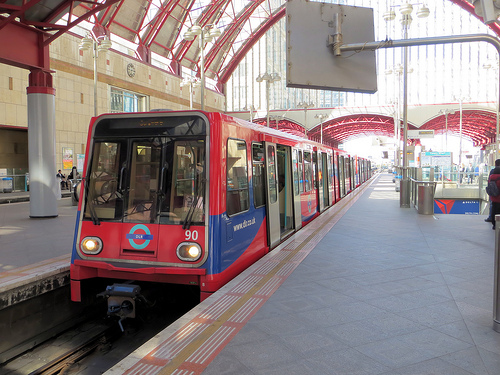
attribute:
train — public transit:
[66, 106, 376, 322]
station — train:
[1, 0, 498, 370]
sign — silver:
[283, 0, 377, 95]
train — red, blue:
[80, 96, 383, 293]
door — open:
[261, 141, 318, 239]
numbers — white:
[178, 229, 198, 248]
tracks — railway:
[12, 308, 132, 373]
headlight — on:
[81, 236, 98, 252]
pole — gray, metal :
[345, 32, 499, 59]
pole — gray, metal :
[393, 19, 413, 201]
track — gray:
[6, 302, 185, 374]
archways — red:
[248, 111, 498, 154]